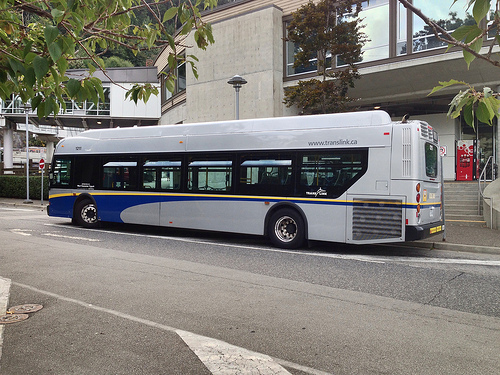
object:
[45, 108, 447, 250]
bus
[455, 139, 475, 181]
vending machine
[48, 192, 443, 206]
yellow stripe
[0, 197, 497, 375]
city street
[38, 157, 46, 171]
stop sign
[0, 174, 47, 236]
corner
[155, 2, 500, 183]
building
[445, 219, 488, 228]
stairs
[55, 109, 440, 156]
white roof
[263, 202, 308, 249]
tire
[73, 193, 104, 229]
tire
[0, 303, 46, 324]
man hole cover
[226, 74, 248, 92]
street light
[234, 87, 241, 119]
metal pole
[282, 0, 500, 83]
large window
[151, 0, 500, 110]
upper floor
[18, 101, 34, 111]
street light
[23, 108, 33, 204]
metal pole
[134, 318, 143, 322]
white lines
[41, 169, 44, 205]
pole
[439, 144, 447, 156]
do not enter sign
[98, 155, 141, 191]
windows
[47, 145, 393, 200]
row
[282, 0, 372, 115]
tree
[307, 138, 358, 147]
www.translink.ca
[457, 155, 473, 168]
soda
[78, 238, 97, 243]
white lines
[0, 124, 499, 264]
traffic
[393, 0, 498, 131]
tree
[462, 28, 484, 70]
leaf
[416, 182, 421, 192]
signal lights